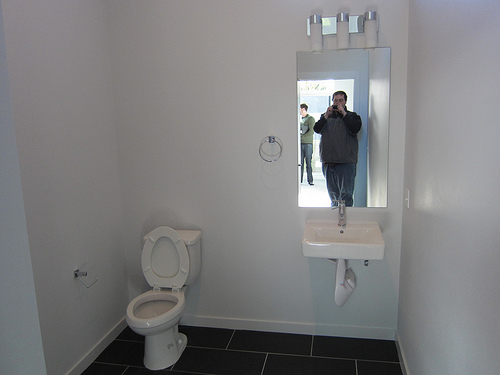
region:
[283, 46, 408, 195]
a bathroom mirror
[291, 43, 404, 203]
a person taking a picture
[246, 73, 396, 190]
a man taking a picture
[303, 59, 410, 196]
taking a picture in the mirror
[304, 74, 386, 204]
man taking picture in the mirror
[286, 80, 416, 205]
person taking picture in the bathroom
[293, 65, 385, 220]
man taking picture in bathroom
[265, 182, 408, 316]
a white bathroom sink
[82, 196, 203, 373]
a white bathroom toilet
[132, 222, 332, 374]
a toilet on black tile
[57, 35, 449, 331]
man taking picture of bathroom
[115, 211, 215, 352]
white ceramic toilet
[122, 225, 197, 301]
white toilet with seat and lid up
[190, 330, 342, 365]
large rectangular black tiles on floor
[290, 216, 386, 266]
small white sink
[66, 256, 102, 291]
toilet paper holder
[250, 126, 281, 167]
small silver towel holder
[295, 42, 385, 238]
rectangular mirror over sink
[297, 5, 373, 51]
silver slights above mirror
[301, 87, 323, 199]
one man in background refelction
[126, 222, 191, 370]
A clean white toilet with the lid and seat up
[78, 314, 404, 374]
A black tile floor with a brick-like pattern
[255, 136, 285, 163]
An empty circular towel holder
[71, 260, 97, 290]
A silver toilet paper holder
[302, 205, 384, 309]
A clean, plain white sink with a high silver faucet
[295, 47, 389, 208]
A tall mirror above the sink with two men reflected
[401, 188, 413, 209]
A white light switch on the white wall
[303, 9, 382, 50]
A light fixture with three separate lighting elements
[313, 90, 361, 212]
A chubby man with short hair taking a photograph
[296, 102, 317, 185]
A thin man waiting in the doorway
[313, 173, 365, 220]
Person wearing dark pants.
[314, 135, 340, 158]
Person wearing gray coat.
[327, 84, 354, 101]
Person has dark brown hair.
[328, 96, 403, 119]
Glasses on person's face.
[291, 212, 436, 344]
Sink is attached to wall.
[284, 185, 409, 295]
Sink is white in color.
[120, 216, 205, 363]
Toilet is white in color.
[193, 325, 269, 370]
Dark ceramic tiles on the ground.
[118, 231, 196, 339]
Toilet seat is up.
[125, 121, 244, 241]
Walls are painted white in bathroom.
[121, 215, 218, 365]
The toilet.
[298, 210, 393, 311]
The bathroom sink.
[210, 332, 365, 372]
Black tile in the bathroom.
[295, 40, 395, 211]
The bathroom mirror.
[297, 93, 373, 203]
Two men are reflected in the bathroom mirror.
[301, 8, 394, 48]
Three lights are above the mirror.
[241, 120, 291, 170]
An empty towel rack.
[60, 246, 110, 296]
A toilet paper roll holder.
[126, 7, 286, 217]
The white wall in the bathroom.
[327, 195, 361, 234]
The faucet on the bathroom sink.